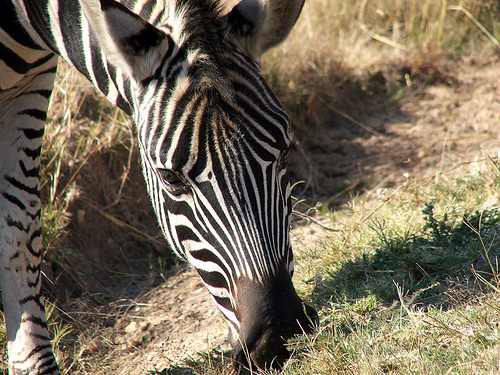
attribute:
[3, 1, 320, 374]
zebra — watching, female, listening, alert, enjoying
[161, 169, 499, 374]
grass — green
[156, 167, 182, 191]
eye — black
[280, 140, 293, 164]
eye — black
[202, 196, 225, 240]
stripes — white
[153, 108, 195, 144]
stripes — black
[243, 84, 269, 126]
stripes — white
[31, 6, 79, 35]
stripes — white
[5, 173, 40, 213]
stripes — white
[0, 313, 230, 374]
grass — green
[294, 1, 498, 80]
grass — brown, tall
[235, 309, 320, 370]
nose — black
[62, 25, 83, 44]
stripes — black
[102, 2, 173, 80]
ear — black, white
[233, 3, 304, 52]
ear — black, white